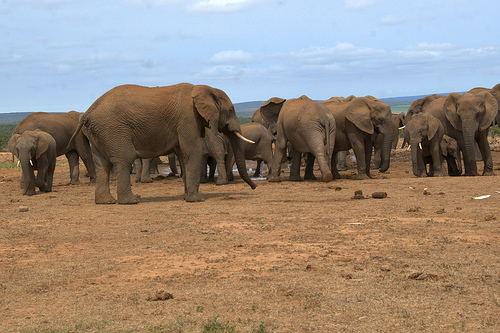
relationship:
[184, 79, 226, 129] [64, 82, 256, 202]
big ear on elephant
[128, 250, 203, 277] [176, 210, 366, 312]
dirt in grass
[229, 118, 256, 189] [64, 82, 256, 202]
trunk on elephant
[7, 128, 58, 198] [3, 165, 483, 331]
elephant on ground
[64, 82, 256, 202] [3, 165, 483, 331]
elephant on ground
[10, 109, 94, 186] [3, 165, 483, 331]
elephant on ground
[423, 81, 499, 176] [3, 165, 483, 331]
elephant on ground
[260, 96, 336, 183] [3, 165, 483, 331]
elephant on ground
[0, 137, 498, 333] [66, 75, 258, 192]
dirt under elephant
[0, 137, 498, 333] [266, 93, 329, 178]
dirt under elephant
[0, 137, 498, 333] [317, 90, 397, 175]
dirt under elephant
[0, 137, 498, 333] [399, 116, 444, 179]
dirt under elephant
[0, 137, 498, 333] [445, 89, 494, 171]
dirt under elephant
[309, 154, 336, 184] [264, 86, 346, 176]
leg of elephant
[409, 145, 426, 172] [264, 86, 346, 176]
leg of elephant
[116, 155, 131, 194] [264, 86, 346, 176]
leg of elephant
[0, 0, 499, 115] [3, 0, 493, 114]
cloud in sky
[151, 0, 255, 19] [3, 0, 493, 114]
cloud in sky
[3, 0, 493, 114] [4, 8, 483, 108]
sky in background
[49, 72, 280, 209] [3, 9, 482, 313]
elephant in photo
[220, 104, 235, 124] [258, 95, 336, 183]
eye of elephant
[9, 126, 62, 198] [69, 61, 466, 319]
baby elephant walking towards camers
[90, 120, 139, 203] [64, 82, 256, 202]
leg of an elephant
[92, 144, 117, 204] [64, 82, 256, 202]
leg of an elephant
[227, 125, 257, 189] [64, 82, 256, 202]
trunk of an elephant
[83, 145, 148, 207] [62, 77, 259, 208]
rear legs of an elephant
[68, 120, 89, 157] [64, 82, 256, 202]
tail of an elephant